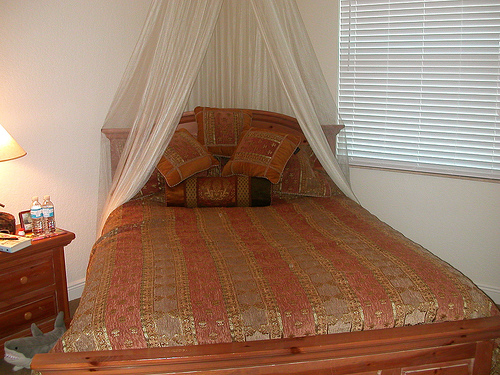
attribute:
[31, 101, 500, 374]
bed — wood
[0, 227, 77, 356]
night stand — oak, red, wooden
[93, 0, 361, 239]
mosquito net — sheer white, white, hanging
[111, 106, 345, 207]
pillows — decorative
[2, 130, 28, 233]
lamp — white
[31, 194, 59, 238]
water bottles — plastic, clear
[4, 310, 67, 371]
whale — stuffed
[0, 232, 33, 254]
book — closed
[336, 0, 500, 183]
blinds — white, plain, closed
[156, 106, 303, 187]
pillows — orange, brown, throw pillows, square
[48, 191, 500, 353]
comforter — detailed, orange, brown, tan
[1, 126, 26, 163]
shade — white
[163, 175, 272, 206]
pillow — circular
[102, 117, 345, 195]
frame — oak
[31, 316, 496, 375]
foot board — wooden